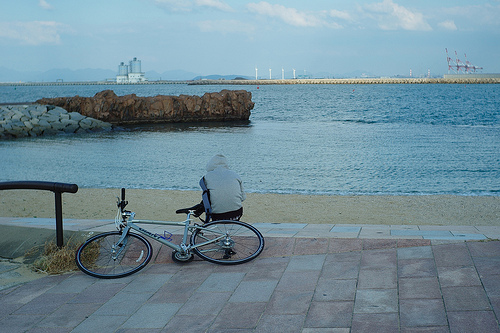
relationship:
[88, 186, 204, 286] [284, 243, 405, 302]
bicycle laying on walkway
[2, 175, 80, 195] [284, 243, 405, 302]
railing on walkway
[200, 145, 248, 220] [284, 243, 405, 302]
person sitting on walkway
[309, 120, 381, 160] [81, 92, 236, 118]
water has cliff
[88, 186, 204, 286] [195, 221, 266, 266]
bicycle has tires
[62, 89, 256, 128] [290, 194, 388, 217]
water lapping sand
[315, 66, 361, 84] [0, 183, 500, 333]
distance has strip of ground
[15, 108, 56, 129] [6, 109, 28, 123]
barrier blocks of gray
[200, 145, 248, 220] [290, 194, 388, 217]
person crouched on sand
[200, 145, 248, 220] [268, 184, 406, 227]
man sitting on beach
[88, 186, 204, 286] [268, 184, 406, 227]
bicycle lying down by beach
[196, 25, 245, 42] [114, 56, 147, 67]
background has buildings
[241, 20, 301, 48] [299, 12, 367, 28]
sky has clouds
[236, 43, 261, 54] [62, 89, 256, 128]
bird flying over water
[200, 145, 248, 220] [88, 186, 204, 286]
person sitting by bicycle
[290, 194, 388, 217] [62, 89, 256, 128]
sand by water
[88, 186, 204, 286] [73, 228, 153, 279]
bicycle has front tire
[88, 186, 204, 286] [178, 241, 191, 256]
bicycle has petal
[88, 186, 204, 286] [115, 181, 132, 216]
bicycle has handlebars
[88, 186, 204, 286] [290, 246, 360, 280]
bicycle on ground